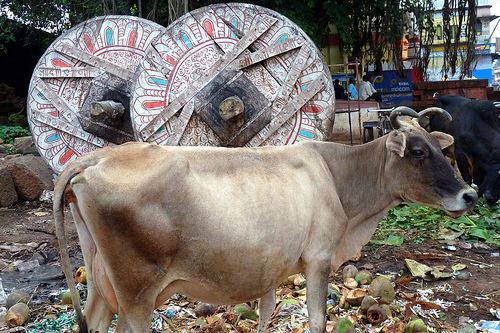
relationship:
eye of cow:
[409, 148, 427, 158] [59, 107, 491, 324]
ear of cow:
[375, 130, 420, 163] [59, 107, 491, 324]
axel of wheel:
[218, 95, 245, 123] [129, 0, 336, 148]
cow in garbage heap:
[303, 100, 498, 280] [339, 271, 423, 331]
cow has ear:
[59, 107, 491, 324] [381, 122, 407, 162]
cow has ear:
[59, 107, 491, 324] [425, 124, 459, 152]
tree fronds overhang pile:
[465, 0, 481, 79] [371, 196, 498, 247]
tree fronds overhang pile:
[453, 0, 464, 73] [371, 196, 498, 247]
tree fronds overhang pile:
[387, 1, 405, 76] [371, 196, 498, 247]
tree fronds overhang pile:
[368, 0, 384, 77] [371, 196, 498, 247]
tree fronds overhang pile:
[441, 1, 453, 78] [371, 196, 498, 247]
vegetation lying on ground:
[10, 260, 472, 331] [5, 163, 498, 330]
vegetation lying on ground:
[365, 200, 499, 243] [5, 163, 498, 330]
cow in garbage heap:
[59, 107, 491, 324] [5, 271, 423, 332]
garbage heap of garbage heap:
[5, 271, 423, 332] [5, 271, 423, 332]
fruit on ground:
[345, 269, 394, 333] [5, 209, 484, 319]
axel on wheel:
[218, 95, 245, 123] [31, 9, 349, 256]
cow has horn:
[59, 107, 491, 324] [385, 103, 425, 128]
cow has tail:
[52, 106, 480, 333] [36, 149, 124, 316]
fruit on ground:
[345, 269, 395, 323] [3, 273, 426, 327]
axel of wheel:
[191, 92, 259, 124] [132, 9, 335, 156]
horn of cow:
[388, 103, 419, 133] [206, 139, 393, 302]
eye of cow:
[407, 143, 426, 160] [50, 130, 462, 323]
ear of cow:
[385, 130, 407, 158] [59, 107, 491, 324]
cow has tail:
[52, 106, 480, 333] [48, 165, 104, 330]